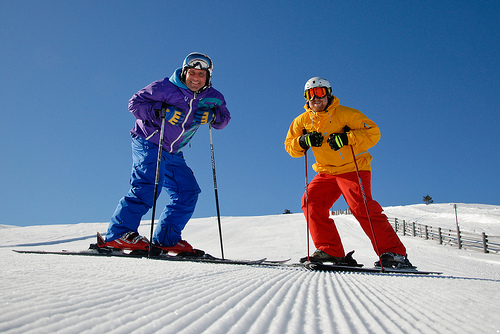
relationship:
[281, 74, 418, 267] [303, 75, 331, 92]
man wearing helmet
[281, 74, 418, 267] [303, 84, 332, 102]
man wearing protective goggles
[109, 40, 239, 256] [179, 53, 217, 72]
man wearing protective goggles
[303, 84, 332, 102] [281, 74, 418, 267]
protective goggles of man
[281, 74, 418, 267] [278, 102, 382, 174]
man wearing jacket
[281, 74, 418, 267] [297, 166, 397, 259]
man wearing ski pants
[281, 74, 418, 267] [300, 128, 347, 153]
man wearing gloves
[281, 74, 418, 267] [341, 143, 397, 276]
man holding ski pole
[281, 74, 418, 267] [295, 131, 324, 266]
man holding ski pole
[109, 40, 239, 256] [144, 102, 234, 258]
man holding ski poles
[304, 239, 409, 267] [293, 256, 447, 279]
boots and skis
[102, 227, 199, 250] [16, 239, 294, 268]
boots and skis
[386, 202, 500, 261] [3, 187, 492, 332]
fence on snow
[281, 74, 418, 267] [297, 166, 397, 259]
man has ski pants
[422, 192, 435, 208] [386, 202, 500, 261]
tree behind fence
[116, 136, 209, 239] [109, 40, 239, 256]
ski pants of man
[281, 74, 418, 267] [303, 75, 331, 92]
man has a helmet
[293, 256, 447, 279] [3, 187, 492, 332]
skis in snow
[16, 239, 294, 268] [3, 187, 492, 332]
skis in snow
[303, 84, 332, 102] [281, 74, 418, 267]
protective goggles on man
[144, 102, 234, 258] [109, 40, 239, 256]
ski poles of man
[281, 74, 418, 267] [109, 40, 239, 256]
man beside man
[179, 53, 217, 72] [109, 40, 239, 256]
goggles on man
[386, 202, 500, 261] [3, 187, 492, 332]
fence along snow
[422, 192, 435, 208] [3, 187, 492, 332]
tree atop snow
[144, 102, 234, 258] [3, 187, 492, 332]
ski poles in snow